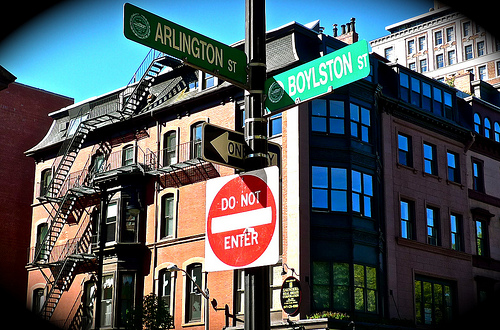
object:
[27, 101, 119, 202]
escape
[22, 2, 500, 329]
building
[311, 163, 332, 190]
window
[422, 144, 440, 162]
window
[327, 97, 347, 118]
window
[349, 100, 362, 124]
window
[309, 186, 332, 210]
window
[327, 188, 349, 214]
window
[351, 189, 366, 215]
window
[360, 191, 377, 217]
window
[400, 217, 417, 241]
window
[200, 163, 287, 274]
sign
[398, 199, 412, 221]
window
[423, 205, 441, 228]
window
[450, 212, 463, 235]
window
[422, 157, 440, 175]
window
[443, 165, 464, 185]
window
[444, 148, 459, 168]
window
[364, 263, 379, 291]
window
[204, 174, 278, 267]
circle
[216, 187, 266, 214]
writing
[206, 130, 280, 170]
arrow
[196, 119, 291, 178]
sign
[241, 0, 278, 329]
pole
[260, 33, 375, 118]
street sign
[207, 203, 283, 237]
line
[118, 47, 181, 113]
staircase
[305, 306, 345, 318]
plants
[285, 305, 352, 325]
column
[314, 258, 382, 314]
reflection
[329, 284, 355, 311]
windows